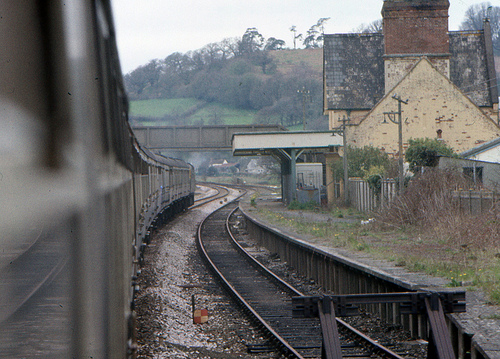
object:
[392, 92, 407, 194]
power pole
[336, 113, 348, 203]
power pole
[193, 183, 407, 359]
train tracks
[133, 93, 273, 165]
terrain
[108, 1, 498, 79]
sky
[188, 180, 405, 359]
track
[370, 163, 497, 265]
brush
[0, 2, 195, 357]
train cars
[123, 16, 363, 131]
trees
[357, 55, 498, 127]
house`s top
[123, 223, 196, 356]
stones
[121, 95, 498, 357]
ground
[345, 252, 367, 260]
dirt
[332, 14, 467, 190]
building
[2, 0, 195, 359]
train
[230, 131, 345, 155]
awning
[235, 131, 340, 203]
patio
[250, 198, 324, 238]
dandelions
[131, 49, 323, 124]
hill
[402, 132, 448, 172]
tree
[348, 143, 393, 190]
tree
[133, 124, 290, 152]
bridge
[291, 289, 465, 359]
barricade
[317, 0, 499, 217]
brick building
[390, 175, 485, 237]
bushes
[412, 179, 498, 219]
fence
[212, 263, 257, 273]
wood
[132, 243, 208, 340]
rocks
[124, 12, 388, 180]
hillside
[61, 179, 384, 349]
set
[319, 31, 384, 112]
roof